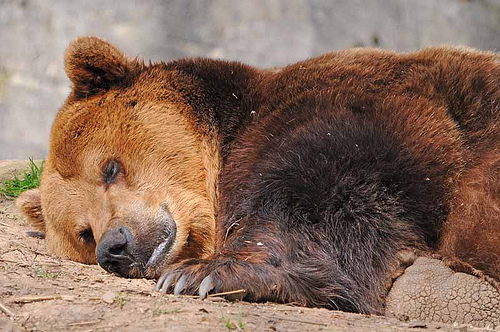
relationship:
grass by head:
[2, 156, 40, 187] [15, 37, 234, 259]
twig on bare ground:
[9, 287, 66, 306] [2, 250, 396, 327]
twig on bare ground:
[179, 283, 245, 297] [2, 250, 396, 327]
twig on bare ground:
[0, 302, 16, 320] [2, 250, 396, 327]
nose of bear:
[84, 204, 152, 275] [50, 46, 431, 231]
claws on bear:
[149, 270, 219, 300] [50, 46, 431, 231]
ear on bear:
[14, 185, 48, 230] [50, 46, 431, 231]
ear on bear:
[46, 23, 134, 102] [50, 46, 431, 231]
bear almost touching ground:
[50, 46, 431, 231] [0, 157, 499, 329]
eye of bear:
[65, 218, 104, 255] [50, 46, 431, 231]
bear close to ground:
[50, 46, 431, 231] [4, 170, 456, 326]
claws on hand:
[149, 270, 219, 300] [155, 253, 305, 307]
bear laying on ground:
[50, 46, 431, 231] [0, 157, 499, 329]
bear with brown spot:
[50, 46, 431, 231] [424, 60, 495, 155]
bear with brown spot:
[50, 46, 431, 231] [172, 58, 264, 143]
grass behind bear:
[2, 156, 40, 187] [50, 46, 431, 231]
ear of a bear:
[46, 23, 134, 102] [50, 46, 431, 231]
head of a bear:
[15, 37, 234, 259] [50, 46, 431, 231]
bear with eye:
[50, 46, 431, 231] [95, 154, 126, 192]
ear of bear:
[46, 23, 134, 102] [50, 46, 431, 231]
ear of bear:
[14, 185, 48, 230] [50, 46, 431, 231]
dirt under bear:
[0, 197, 498, 329] [50, 46, 431, 231]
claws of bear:
[149, 270, 219, 300] [18, 23, 497, 330]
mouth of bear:
[136, 201, 177, 279] [50, 46, 431, 231]